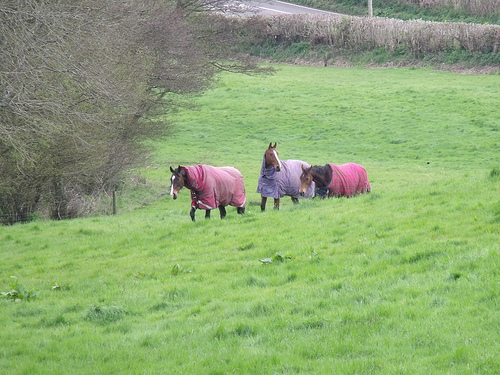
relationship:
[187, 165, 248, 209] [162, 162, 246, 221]
blanket for a horse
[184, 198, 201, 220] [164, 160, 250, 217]
leg on a horse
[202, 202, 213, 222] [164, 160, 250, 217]
leg on a horse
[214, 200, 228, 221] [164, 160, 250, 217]
leg on a horse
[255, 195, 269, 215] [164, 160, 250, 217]
leg on a horse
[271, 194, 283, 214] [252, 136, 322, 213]
leg on a horse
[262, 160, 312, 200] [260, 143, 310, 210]
covering on horse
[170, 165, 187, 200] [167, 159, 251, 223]
head of horse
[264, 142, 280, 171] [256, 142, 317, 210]
head of horse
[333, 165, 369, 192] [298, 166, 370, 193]
cover on horse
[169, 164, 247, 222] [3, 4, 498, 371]
horse are outside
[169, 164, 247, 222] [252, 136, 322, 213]
horse next to horse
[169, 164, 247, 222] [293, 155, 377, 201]
horse next to horse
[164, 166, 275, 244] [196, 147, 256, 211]
horse wearing blanket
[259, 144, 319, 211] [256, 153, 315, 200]
horse wearing covering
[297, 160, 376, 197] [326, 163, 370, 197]
horse wearing cover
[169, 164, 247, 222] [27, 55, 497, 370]
horse in field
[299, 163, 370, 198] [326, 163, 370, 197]
horse covered in cover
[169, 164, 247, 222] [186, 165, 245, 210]
horse covered in blanket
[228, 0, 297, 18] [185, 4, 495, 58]
line on road